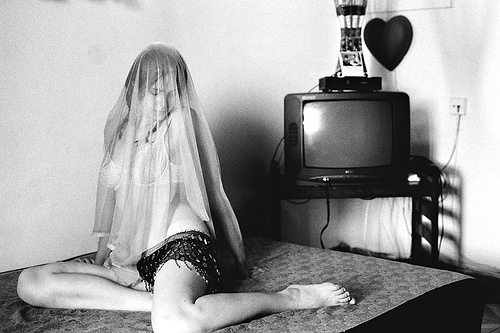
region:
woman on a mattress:
[23, 44, 360, 331]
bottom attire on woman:
[113, 230, 224, 284]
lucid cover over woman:
[78, 43, 244, 260]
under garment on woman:
[92, 120, 193, 197]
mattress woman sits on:
[2, 233, 469, 331]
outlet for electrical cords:
[443, 93, 473, 120]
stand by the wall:
[288, 160, 465, 245]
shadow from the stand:
[439, 163, 477, 272]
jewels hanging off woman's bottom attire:
[173, 257, 195, 273]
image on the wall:
[358, 3, 461, 15]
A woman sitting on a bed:
[2, 39, 489, 330]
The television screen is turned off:
[283, 88, 415, 186]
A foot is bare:
[281, 276, 360, 314]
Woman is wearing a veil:
[86, 39, 252, 289]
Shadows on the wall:
[407, 106, 470, 270]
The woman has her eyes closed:
[121, 38, 183, 125]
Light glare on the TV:
[298, 102, 324, 139]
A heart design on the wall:
[362, 12, 415, 75]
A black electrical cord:
[316, 196, 335, 252]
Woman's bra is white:
[95, 108, 191, 191]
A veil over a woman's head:
[85, 39, 253, 277]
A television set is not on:
[279, 87, 415, 184]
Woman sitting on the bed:
[2, 35, 482, 330]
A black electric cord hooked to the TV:
[316, 199, 338, 249]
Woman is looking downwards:
[109, 40, 190, 123]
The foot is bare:
[279, 277, 364, 317]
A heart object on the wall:
[360, 11, 417, 76]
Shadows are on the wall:
[352, 2, 497, 272]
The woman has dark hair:
[114, 40, 191, 146]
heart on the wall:
[349, 9, 419, 84]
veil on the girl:
[91, 40, 232, 243]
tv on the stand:
[273, 84, 420, 181]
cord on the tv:
[302, 193, 336, 250]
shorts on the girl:
[125, 237, 218, 282]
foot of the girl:
[278, 283, 354, 305]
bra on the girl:
[93, 140, 175, 194]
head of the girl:
[119, 48, 189, 122]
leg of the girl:
[203, 284, 308, 324]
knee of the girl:
[12, 267, 79, 307]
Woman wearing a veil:
[85, 36, 230, 267]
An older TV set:
[275, 85, 415, 191]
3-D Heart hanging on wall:
[355, 5, 417, 70]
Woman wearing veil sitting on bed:
[11, 35, 356, 322]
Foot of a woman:
[270, 267, 362, 317]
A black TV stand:
[257, 162, 454, 277]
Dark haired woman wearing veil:
[87, 35, 207, 255]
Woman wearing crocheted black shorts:
[106, 230, 226, 295]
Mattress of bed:
[5, 215, 491, 325]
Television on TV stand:
[273, 80, 454, 285]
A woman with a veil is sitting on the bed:
[18, 47, 360, 330]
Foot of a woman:
[283, 280, 357, 309]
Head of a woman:
[125, 45, 191, 127]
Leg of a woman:
[197, 288, 278, 325]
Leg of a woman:
[62, 273, 144, 315]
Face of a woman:
[149, 81, 178, 117]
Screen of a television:
[303, 100, 393, 167]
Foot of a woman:
[282, 276, 359, 315]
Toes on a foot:
[329, 277, 359, 314]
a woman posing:
[10, 38, 414, 330]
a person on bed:
[8, 220, 479, 332]